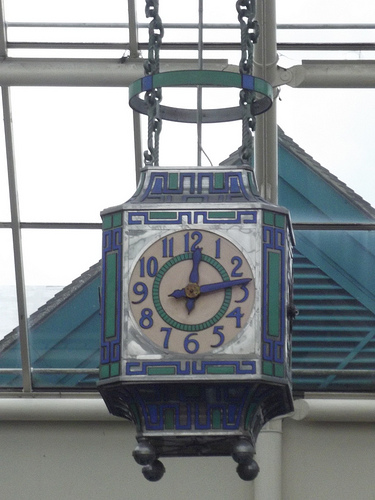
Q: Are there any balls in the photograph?
A: Yes, there is a ball.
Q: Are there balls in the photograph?
A: Yes, there is a ball.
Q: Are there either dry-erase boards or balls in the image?
A: Yes, there is a ball.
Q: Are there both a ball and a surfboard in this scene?
A: No, there is a ball but no surfboards.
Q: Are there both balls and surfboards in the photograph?
A: No, there is a ball but no surfboards.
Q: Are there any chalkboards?
A: No, there are no chalkboards.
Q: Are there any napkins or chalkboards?
A: No, there are no chalkboards or napkins.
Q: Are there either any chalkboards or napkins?
A: No, there are no chalkboards or napkins.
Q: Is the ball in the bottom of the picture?
A: Yes, the ball is in the bottom of the image.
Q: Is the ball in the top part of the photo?
A: No, the ball is in the bottom of the image.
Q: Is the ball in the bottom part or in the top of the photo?
A: The ball is in the bottom of the image.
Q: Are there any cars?
A: No, there are no cars.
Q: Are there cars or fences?
A: No, there are no cars or fences.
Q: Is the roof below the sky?
A: Yes, the roof is below the sky.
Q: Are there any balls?
A: Yes, there is a ball.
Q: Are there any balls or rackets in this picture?
A: Yes, there is a ball.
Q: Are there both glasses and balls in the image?
A: No, there is a ball but no glasses.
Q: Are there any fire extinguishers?
A: No, there are no fire extinguishers.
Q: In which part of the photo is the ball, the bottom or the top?
A: The ball is in the bottom of the image.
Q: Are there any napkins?
A: No, there are no napkins.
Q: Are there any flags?
A: No, there are no flags.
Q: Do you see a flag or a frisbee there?
A: No, there are no flags or frisbees.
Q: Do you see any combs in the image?
A: No, there are no combs.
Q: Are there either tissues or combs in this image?
A: No, there are no combs or tissues.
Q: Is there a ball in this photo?
A: Yes, there is a ball.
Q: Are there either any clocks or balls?
A: Yes, there is a ball.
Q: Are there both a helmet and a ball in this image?
A: No, there is a ball but no helmets.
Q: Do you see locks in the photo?
A: No, there are no locks.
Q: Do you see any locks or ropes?
A: No, there are no locks or ropes.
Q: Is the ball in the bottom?
A: Yes, the ball is in the bottom of the image.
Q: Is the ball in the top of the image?
A: No, the ball is in the bottom of the image.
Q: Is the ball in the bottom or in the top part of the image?
A: The ball is in the bottom of the image.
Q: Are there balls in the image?
A: Yes, there is a ball.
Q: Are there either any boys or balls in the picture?
A: Yes, there is a ball.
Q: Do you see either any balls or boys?
A: Yes, there is a ball.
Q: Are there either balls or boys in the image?
A: Yes, there is a ball.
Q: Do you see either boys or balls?
A: Yes, there is a ball.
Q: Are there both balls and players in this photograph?
A: No, there is a ball but no players.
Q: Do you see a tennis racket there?
A: No, there are no rackets.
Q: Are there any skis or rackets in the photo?
A: No, there are no rackets or skis.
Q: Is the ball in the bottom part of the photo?
A: Yes, the ball is in the bottom of the image.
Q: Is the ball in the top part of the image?
A: No, the ball is in the bottom of the image.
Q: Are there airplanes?
A: No, there are no airplanes.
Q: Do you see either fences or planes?
A: No, there are no planes or fences.